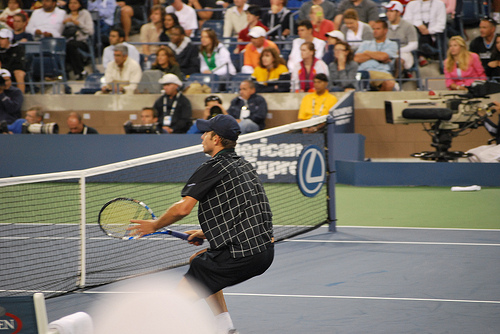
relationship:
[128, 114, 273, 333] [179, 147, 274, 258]
man wearing plaid shirt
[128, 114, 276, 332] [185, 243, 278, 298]
man wearing black shorts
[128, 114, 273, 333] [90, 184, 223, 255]
man holding racket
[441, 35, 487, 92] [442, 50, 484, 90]
woman wearing a blazer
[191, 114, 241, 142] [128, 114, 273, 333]
cap on a man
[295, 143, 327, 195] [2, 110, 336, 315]
design on a ten net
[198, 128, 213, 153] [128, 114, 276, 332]
face of a man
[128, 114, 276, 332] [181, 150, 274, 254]
man wearing a shirt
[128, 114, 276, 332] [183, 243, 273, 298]
man wearing a black shorts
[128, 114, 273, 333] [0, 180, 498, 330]
man on tennis court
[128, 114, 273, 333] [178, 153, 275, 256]
man wearing plaid shirt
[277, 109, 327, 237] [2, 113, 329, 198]
net has trim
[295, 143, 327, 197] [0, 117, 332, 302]
design on net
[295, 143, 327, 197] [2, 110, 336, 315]
design on net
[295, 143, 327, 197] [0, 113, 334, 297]
design on net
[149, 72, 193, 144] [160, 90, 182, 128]
man wearing lanyard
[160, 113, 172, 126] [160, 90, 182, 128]
pass hanging from lanyard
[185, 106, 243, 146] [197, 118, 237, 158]
cap covering head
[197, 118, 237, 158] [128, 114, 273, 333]
head belonging to man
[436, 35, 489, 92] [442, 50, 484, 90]
woman wearing blazer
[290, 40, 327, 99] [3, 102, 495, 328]
person watching match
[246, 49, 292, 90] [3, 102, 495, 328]
person watching match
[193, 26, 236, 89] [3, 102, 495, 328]
person watching match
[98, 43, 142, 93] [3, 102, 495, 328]
person watching match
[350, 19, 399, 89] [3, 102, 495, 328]
person watching match